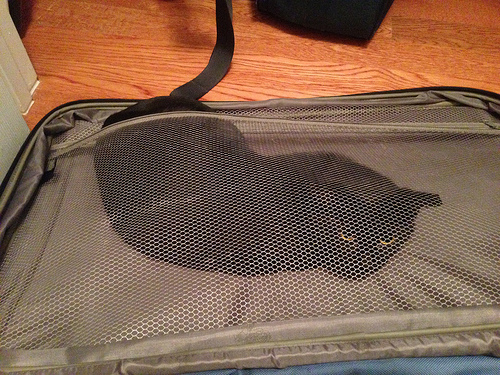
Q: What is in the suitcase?
A: A cat.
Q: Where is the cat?
A: In a suitcase pouch.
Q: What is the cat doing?
A: Trying to hide.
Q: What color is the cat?
A: Black.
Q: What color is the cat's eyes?
A: Yellow.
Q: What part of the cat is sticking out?
A: The tail.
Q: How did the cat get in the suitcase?
A: Crawled in.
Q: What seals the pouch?
A: A zipper.